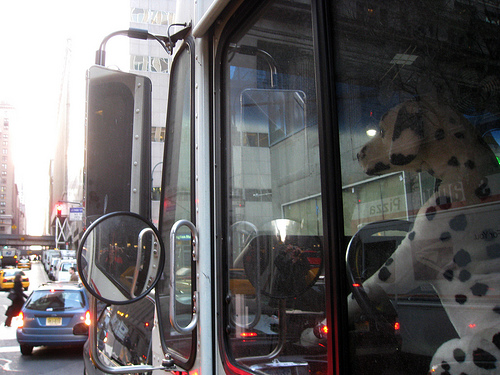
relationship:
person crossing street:
[5, 270, 30, 327] [0, 253, 87, 372]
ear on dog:
[392, 113, 429, 165] [352, 117, 492, 297]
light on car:
[3, 308, 36, 329] [13, 283, 95, 356]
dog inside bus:
[300, 100, 499, 374] [74, 1, 497, 373]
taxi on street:
[1, 266, 29, 291] [8, 237, 110, 372]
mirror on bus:
[81, 211, 162, 307] [74, 1, 497, 373]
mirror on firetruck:
[75, 211, 166, 306] [76, 0, 498, 337]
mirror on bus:
[75, 211, 166, 306] [74, 1, 497, 373]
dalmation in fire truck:
[344, 109, 496, 334] [97, 25, 482, 371]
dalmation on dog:
[344, 109, 496, 334] [300, 100, 499, 374]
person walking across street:
[5, 270, 30, 327] [0, 253, 87, 372]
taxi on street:
[1, 266, 29, 291] [0, 253, 87, 372]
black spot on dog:
[453, 250, 474, 268] [346, 95, 498, 373]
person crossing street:
[5, 270, 30, 327] [1, 263, 96, 373]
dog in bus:
[300, 100, 499, 374] [69, 1, 496, 373]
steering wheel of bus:
[339, 218, 435, 372] [69, 1, 496, 373]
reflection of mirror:
[248, 220, 326, 306] [82, 170, 232, 349]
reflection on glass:
[248, 220, 326, 306] [213, 3, 329, 365]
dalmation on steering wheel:
[344, 109, 496, 334] [327, 205, 429, 342]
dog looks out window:
[361, 89, 498, 374] [130, 25, 472, 374]